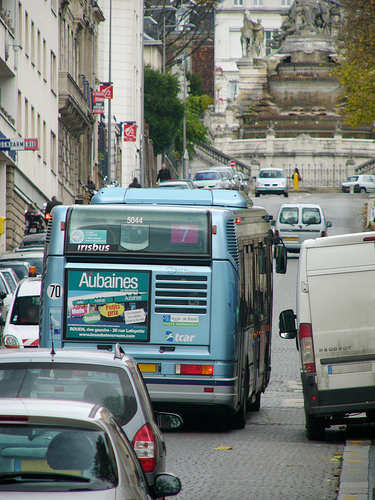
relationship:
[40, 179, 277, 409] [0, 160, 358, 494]
bus moving traffic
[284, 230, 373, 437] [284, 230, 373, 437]
car van car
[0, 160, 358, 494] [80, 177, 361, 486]
vehicles moving street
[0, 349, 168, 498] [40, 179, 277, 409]
two cars bus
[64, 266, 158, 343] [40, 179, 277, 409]
sign on bus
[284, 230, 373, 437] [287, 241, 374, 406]
car white car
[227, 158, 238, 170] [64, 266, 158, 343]
do stop sign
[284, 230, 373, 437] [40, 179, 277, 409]
car van bus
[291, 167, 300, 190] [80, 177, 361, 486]
hydrant pole street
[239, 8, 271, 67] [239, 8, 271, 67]
large on large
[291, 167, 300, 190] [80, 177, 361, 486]
hydrant object street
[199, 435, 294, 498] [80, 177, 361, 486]
cobble stone street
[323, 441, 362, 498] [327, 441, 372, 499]
edge of sidewalk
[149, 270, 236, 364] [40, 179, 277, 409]
blue color bus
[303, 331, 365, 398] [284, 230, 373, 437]
dirt on car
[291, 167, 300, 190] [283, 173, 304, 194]
hydrant fire hydrant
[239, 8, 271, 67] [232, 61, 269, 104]
large on base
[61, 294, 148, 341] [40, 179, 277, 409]
black words bus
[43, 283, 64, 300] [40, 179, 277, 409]
white red bus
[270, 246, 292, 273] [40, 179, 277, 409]
mirror on bus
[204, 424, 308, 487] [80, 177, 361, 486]
part of road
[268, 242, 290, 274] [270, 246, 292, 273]
side of mirror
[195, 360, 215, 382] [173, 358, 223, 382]
part of indicator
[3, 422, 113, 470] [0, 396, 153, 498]
rear window automobile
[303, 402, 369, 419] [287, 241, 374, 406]
bottom of car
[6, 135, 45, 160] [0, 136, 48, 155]
part of banner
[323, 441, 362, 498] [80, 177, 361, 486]
edge of road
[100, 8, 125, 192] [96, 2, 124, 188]
part of post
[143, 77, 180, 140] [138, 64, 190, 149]
part of tree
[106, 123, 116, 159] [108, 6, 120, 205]
part of lamp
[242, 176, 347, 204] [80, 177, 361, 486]
end of street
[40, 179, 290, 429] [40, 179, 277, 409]
bus transportation bus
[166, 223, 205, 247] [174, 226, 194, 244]
route number seven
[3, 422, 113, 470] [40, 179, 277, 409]
rear of bus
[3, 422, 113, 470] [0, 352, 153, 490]
rear of automobile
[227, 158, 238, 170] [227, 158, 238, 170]
do not do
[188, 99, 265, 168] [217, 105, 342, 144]
stairway to fountain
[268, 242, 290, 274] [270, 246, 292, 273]
side view mirror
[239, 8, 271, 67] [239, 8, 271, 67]
large of large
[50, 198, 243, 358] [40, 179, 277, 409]
light blue bus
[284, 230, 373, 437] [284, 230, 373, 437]
car white car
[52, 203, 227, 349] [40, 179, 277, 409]
back of bus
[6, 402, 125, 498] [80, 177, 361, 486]
silver car street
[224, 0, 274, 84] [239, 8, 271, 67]
large stone large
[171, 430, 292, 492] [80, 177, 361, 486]
gray cobblestone street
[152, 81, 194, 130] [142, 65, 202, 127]
green bushes behind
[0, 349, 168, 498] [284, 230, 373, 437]
two cars car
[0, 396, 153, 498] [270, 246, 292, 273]
automobile side mirror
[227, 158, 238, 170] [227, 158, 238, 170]
do street do